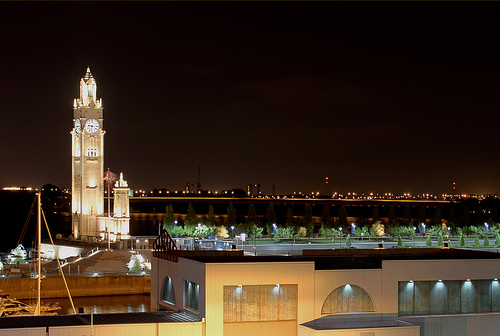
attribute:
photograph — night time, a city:
[3, 0, 499, 334]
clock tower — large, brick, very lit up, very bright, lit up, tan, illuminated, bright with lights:
[71, 67, 108, 240]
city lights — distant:
[0, 180, 496, 228]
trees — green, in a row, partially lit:
[160, 200, 498, 251]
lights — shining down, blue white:
[152, 276, 499, 302]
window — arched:
[322, 283, 386, 318]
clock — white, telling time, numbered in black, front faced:
[84, 114, 98, 136]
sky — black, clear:
[2, 0, 498, 192]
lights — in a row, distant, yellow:
[129, 191, 469, 208]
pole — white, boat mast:
[32, 189, 48, 316]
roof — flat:
[160, 248, 499, 270]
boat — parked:
[0, 292, 67, 320]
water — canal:
[4, 291, 157, 310]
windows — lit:
[220, 284, 498, 320]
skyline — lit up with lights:
[3, 139, 499, 216]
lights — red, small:
[450, 179, 459, 192]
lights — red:
[323, 174, 338, 184]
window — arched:
[159, 271, 176, 308]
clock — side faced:
[72, 120, 82, 131]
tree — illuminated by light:
[164, 200, 186, 244]